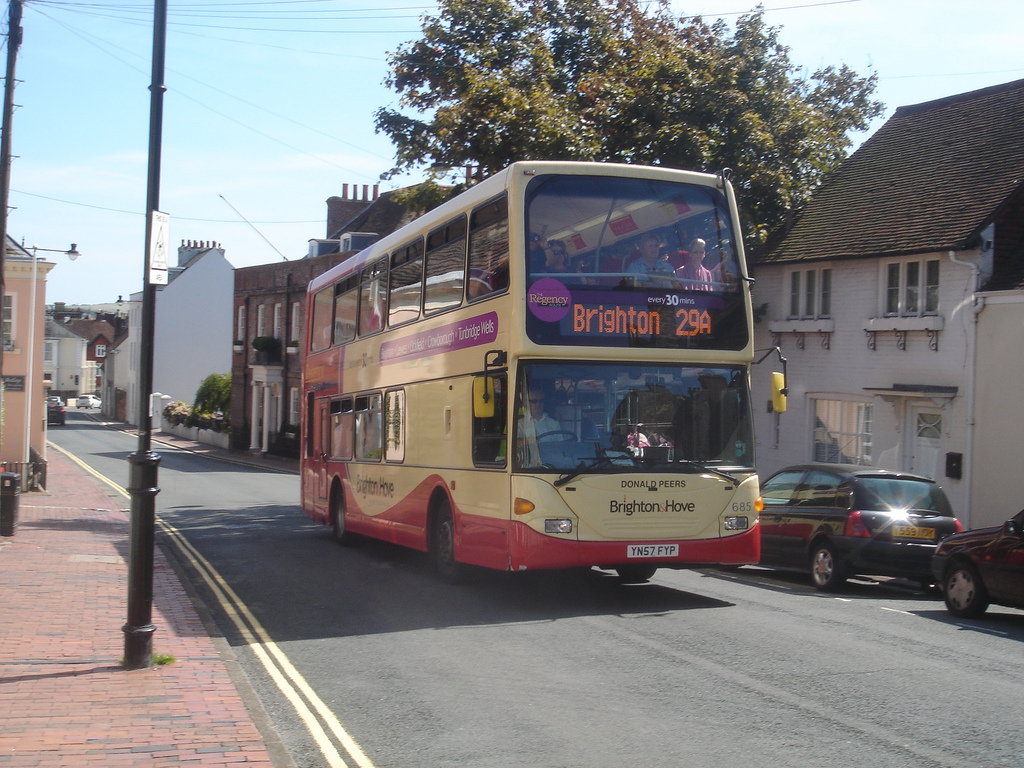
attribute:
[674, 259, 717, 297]
man shirt — pink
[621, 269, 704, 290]
man arms — folded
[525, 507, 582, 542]
bus headlight — white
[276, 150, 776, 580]
bus — red, white